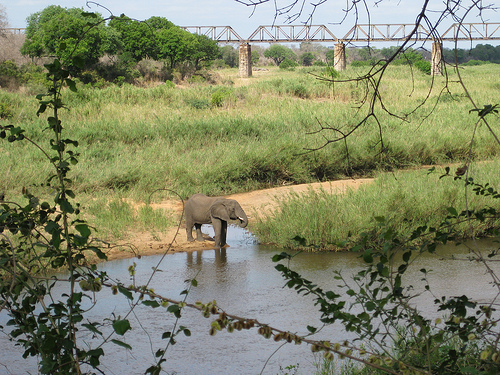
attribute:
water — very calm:
[3, 228, 499, 373]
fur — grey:
[194, 200, 236, 225]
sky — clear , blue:
[4, 1, 496, 46]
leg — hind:
[177, 222, 202, 242]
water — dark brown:
[99, 259, 488, 371]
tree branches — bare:
[336, 45, 412, 157]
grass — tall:
[119, 74, 274, 174]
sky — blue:
[4, 7, 484, 43]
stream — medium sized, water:
[21, 230, 485, 356]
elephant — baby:
[183, 191, 247, 245]